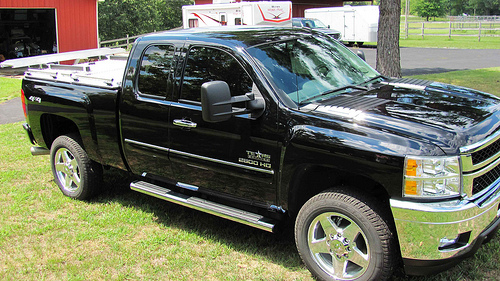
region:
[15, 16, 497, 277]
A black pick-up truck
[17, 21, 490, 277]
A black pick-up truck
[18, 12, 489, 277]
A black pick-up truck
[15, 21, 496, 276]
A black pick-up truck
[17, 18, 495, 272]
large black truck on grass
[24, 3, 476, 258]
large black truck on grass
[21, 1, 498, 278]
large black truck on grass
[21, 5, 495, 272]
large black truck on grass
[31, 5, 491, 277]
large black truck on grass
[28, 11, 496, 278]
large black truck on grass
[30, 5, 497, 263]
large black truck on grass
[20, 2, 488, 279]
large black truck on grass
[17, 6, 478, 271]
large black truck on grass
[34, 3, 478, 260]
large black truck on grass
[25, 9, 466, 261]
large black truck on grass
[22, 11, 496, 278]
large black truck on grass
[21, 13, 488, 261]
large black truck on grass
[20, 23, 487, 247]
large black truck on grass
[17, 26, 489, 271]
a big black pick up truck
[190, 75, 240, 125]
the mirror of a pick up truck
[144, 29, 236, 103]
the side window of a pick up truck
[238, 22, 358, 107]
the front window of a pick up truck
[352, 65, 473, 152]
the hood of a pick up truck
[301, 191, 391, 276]
the front wheel of a pick up truck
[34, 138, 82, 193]
the back wheel of a pick up truck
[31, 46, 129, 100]
the bed of a pick up truck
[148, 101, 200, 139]
the hand of a pick up truck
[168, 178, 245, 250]
the step of a pick up truck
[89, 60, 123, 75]
Bed of a pick up truck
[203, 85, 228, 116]
A black side mirror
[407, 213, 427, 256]
Grass surface reflecting on fender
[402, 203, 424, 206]
Reflection of light on metallic surface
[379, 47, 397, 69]
Tree trunk on side of truck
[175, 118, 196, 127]
Pick up door handle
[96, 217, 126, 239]
Green grass next to vehicle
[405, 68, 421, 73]
Shadow cas by the tree